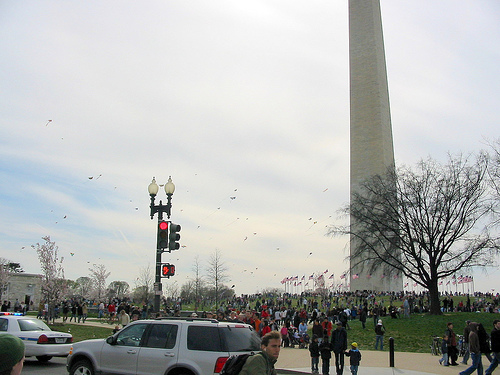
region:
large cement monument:
[346, 3, 406, 296]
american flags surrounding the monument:
[278, 267, 478, 304]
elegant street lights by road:
[147, 177, 177, 323]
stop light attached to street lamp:
[157, 218, 182, 254]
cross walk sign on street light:
[160, 265, 176, 278]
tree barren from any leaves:
[322, 149, 498, 314]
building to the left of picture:
[1, 269, 61, 317]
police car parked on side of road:
[1, 309, 73, 365]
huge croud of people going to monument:
[2, 285, 499, 373]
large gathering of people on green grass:
[148, 283, 483, 355]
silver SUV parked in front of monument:
[65, 308, 269, 371]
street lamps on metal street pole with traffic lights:
[136, 174, 186, 307]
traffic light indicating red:
[153, 215, 170, 258]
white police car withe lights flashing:
[6, 300, 80, 362]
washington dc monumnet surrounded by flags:
[341, 0, 412, 312]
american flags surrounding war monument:
[281, 268, 481, 293]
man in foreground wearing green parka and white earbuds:
[244, 330, 286, 372]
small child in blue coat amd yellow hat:
[340, 337, 366, 372]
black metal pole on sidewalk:
[386, 333, 401, 367]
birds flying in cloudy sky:
[21, 100, 420, 279]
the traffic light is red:
[102, 142, 212, 242]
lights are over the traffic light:
[92, 166, 235, 278]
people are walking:
[55, 305, 90, 324]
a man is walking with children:
[292, 315, 377, 362]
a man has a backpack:
[212, 343, 327, 373]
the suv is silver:
[102, 313, 294, 374]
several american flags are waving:
[270, 262, 429, 318]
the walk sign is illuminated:
[145, 248, 218, 318]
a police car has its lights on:
[8, 295, 59, 370]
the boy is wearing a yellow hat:
[340, 338, 397, 370]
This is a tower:
[284, 67, 439, 224]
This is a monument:
[350, 69, 380, 148]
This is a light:
[91, 104, 196, 265]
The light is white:
[123, 136, 229, 226]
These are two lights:
[120, 146, 275, 248]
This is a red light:
[123, 183, 200, 305]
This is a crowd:
[246, 261, 325, 361]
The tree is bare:
[353, 166, 468, 309]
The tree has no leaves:
[360, 173, 434, 323]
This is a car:
[130, 264, 189, 357]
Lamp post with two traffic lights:
[144, 174, 181, 315]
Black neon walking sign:
[160, 263, 177, 278]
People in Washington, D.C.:
[1, 0, 496, 373]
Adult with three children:
[307, 320, 362, 374]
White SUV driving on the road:
[65, 313, 264, 374]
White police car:
[0, 307, 74, 366]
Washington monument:
[340, 0, 407, 295]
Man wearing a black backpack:
[220, 328, 282, 373]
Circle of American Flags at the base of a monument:
[280, 269, 475, 295]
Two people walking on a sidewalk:
[460, 318, 499, 374]